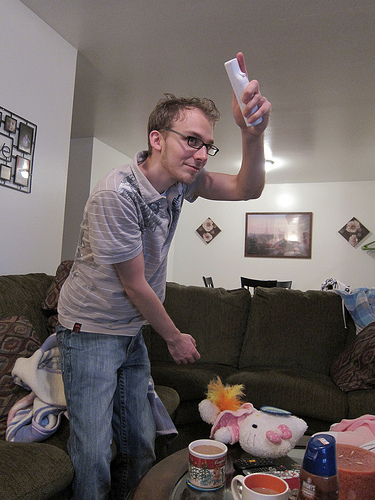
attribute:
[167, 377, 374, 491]
table — cluttered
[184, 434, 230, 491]
mug — coffee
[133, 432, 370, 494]
table — coffee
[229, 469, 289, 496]
mug — orange, white, coffee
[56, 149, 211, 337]
shirt — grey, white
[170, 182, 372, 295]
wall — decorated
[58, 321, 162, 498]
jeans — blue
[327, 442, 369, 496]
candle — large